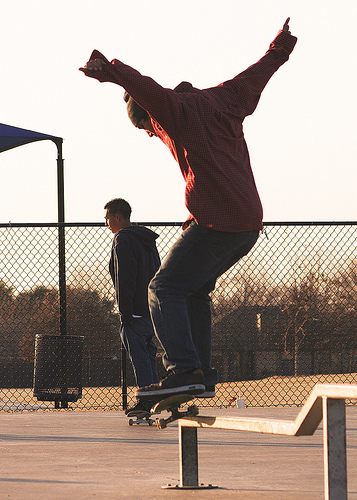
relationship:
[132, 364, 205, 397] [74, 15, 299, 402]
foot of a guy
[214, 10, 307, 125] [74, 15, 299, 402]
arm of guy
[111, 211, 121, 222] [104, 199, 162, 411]
ear of person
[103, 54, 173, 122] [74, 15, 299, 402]
arm belonging to guy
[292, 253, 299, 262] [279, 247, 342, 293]
hole built into fence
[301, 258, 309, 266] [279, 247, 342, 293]
hole built into fence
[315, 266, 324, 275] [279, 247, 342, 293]
hole built into fence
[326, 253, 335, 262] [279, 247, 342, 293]
hole built into fence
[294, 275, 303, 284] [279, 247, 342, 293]
hole built into fence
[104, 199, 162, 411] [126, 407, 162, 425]
person standing on skateboard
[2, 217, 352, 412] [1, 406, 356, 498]
fence surrounding area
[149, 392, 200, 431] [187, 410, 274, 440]
skateboard skating on ramp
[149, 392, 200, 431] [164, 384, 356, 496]
skateboard coming off ramp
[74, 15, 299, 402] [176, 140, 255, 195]
guy wearing jacket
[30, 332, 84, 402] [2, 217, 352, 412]
bin standing outside fence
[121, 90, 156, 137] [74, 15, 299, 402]
head belonging to guy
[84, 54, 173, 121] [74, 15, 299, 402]
arm belonging to guy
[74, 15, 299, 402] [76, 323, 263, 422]
guy on skateboard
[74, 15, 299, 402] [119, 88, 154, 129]
guy wearing cap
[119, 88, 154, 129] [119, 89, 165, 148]
cap on head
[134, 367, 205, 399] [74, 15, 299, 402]
feet of guy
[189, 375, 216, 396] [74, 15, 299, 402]
feet of guy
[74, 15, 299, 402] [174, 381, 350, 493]
guy skateboarding on rail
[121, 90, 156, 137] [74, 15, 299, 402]
head on guy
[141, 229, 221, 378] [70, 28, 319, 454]
leg on person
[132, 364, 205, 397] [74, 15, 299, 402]
foot on guy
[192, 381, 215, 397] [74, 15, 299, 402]
foot on guy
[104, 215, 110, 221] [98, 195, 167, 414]
eye on person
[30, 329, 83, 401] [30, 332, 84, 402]
holes in bin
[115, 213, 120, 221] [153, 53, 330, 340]
ear on person